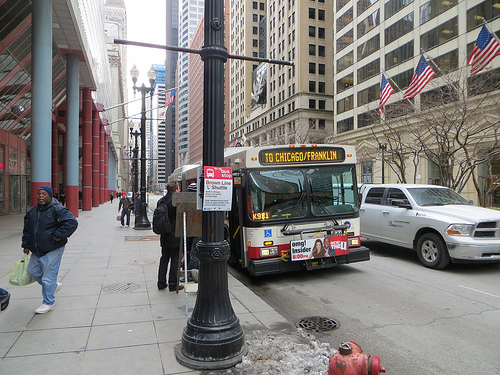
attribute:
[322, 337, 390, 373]
hydrant — red, fire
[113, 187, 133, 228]
person — standing up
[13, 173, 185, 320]
people — outdoors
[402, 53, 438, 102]
flag — waving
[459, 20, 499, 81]
flag — waving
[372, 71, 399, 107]
flag — waving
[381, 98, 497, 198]
tree — brown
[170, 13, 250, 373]
pole — black, metal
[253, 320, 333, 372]
snow — dirty